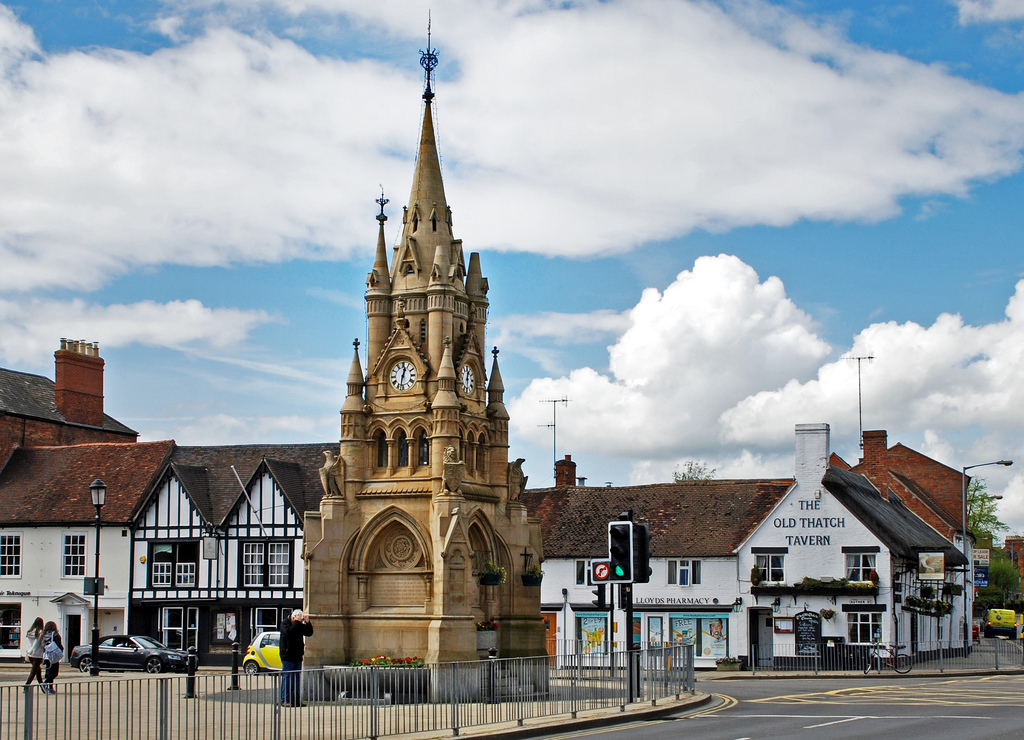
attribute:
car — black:
[73, 611, 195, 678]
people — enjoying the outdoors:
[19, 612, 71, 692]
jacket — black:
[276, 619, 313, 659]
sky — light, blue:
[0, 1, 1022, 561]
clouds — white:
[4, 9, 1020, 543]